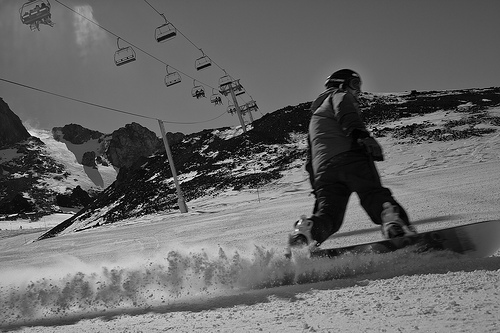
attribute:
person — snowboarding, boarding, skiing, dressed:
[289, 68, 418, 247]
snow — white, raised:
[2, 236, 455, 324]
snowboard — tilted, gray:
[286, 229, 474, 253]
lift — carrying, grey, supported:
[2, 1, 265, 212]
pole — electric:
[159, 119, 190, 214]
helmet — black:
[326, 68, 361, 92]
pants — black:
[308, 149, 411, 242]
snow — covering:
[24, 122, 119, 195]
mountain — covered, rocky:
[1, 93, 189, 222]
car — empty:
[154, 12, 178, 41]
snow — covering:
[2, 134, 494, 332]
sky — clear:
[2, 1, 500, 132]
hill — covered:
[40, 81, 499, 236]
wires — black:
[1, 76, 230, 126]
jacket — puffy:
[305, 89, 370, 175]